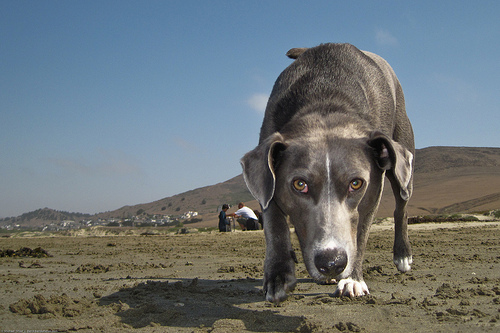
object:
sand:
[0, 233, 498, 333]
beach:
[1, 222, 500, 331]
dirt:
[0, 230, 500, 333]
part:
[87, 254, 180, 287]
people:
[224, 202, 259, 230]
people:
[218, 204, 229, 232]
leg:
[392, 193, 415, 273]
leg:
[331, 197, 373, 298]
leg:
[261, 208, 297, 304]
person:
[218, 203, 229, 232]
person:
[225, 202, 259, 231]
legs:
[259, 210, 298, 304]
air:
[0, 0, 500, 127]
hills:
[0, 144, 500, 225]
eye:
[289, 178, 310, 196]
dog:
[237, 41, 419, 301]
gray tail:
[283, 46, 304, 59]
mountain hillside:
[1, 206, 89, 229]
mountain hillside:
[2, 145, 499, 223]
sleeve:
[234, 208, 244, 216]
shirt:
[235, 206, 259, 220]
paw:
[335, 278, 371, 299]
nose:
[313, 248, 349, 276]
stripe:
[324, 151, 332, 224]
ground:
[0, 0, 500, 214]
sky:
[0, 0, 500, 217]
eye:
[347, 178, 365, 193]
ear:
[370, 137, 415, 197]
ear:
[237, 131, 285, 209]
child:
[218, 204, 231, 232]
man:
[226, 202, 260, 231]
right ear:
[238, 131, 285, 210]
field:
[1, 227, 498, 333]